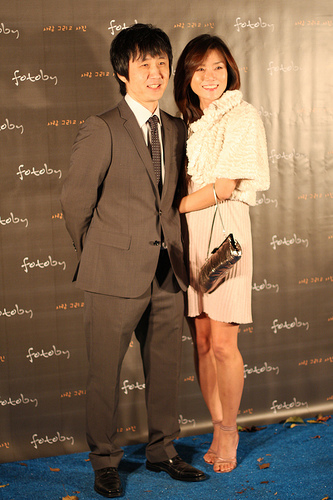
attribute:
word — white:
[10, 69, 61, 87]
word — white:
[16, 162, 63, 180]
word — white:
[232, 17, 276, 33]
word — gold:
[43, 24, 88, 34]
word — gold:
[78, 69, 117, 80]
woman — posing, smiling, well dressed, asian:
[174, 34, 269, 474]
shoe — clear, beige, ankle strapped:
[212, 426, 241, 474]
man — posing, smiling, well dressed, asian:
[58, 22, 205, 496]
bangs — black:
[128, 39, 170, 62]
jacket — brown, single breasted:
[58, 98, 185, 298]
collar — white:
[123, 92, 162, 126]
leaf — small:
[256, 461, 272, 471]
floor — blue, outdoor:
[0, 413, 332, 499]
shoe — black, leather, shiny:
[93, 466, 123, 500]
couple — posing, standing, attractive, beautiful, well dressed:
[58, 23, 271, 496]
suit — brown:
[58, 102, 189, 468]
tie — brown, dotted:
[148, 115, 162, 188]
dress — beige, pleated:
[184, 122, 254, 324]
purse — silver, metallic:
[197, 232, 242, 295]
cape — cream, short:
[186, 91, 272, 206]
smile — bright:
[201, 82, 221, 91]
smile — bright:
[147, 83, 163, 91]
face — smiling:
[190, 57, 228, 99]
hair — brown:
[174, 34, 241, 122]